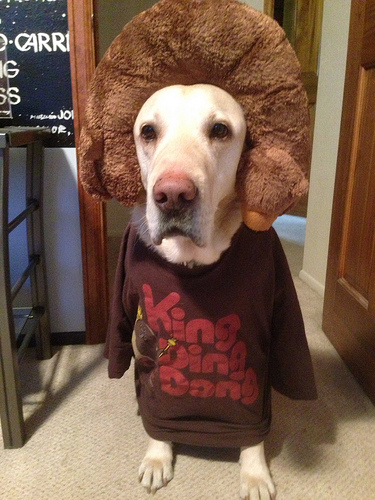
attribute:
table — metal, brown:
[1, 123, 57, 452]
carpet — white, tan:
[3, 202, 375, 496]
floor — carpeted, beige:
[2, 205, 374, 498]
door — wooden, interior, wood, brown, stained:
[324, 4, 373, 401]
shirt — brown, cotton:
[97, 207, 324, 458]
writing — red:
[137, 282, 261, 409]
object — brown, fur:
[74, 2, 312, 239]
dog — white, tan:
[90, 78, 310, 500]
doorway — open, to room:
[93, 2, 354, 343]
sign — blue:
[1, 1, 83, 152]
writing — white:
[1, 30, 74, 137]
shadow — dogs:
[261, 343, 371, 477]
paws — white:
[233, 454, 280, 499]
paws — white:
[134, 441, 177, 495]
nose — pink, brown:
[150, 167, 200, 212]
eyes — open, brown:
[204, 120, 233, 143]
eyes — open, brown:
[134, 120, 158, 144]